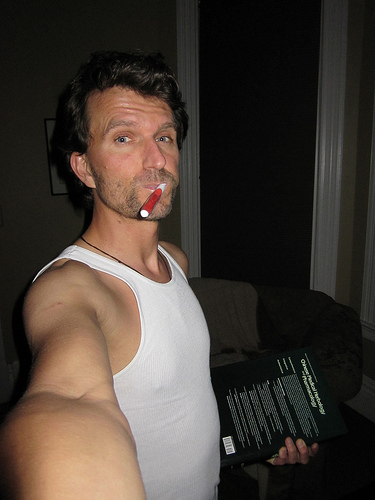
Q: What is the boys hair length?
A: Short.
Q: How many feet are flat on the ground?
A: 1.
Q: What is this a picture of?
A: Man standing.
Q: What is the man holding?
A: Book.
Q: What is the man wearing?
A: Tank top.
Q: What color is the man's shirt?
A: White.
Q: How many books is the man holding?
A: 1.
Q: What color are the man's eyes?
A: Blue.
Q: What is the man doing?
A: Taking a selfie.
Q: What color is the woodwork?
A: White.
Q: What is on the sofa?
A: Brown blanket.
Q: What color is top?
A: White.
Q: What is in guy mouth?
A: Marker.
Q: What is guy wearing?
A: Shirt.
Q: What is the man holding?
A: Book.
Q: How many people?
A: One.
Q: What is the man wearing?
A: T-shirt.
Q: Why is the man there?
A: He's home.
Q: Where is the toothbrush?
A: In the mouth.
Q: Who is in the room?
A: The man.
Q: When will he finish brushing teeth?
A: Soon.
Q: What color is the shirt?
A: White.